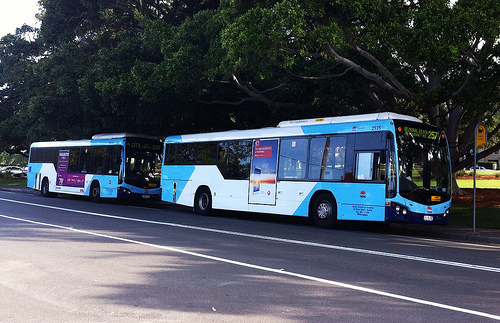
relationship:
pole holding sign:
[470, 122, 480, 232] [476, 124, 486, 147]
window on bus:
[31, 148, 122, 176] [27, 132, 157, 200]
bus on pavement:
[156, 108, 457, 232] [0, 190, 500, 323]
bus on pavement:
[159, 111, 451, 229] [0, 190, 500, 323]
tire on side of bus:
[194, 185, 215, 215] [156, 108, 457, 232]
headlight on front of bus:
[391, 206, 408, 216] [156, 108, 457, 232]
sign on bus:
[387, 115, 445, 142] [154, 99, 475, 223]